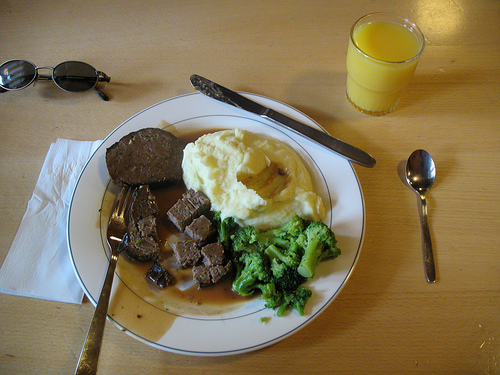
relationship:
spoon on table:
[394, 143, 471, 309] [10, 5, 498, 365]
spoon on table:
[405, 148, 437, 283] [10, 5, 498, 365]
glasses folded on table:
[0, 59, 111, 102] [10, 5, 498, 365]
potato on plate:
[180, 128, 327, 228] [330, 148, 374, 225]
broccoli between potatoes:
[212, 212, 342, 318] [175, 123, 325, 220]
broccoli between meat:
[212, 212, 342, 318] [104, 129, 217, 290]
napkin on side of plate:
[0, 138, 103, 305] [64, 88, 372, 359]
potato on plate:
[180, 128, 327, 228] [64, 88, 372, 359]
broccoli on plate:
[212, 212, 342, 318] [64, 88, 372, 359]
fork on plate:
[73, 182, 166, 373] [64, 88, 372, 359]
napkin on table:
[0, 138, 103, 305] [10, 5, 498, 365]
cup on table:
[343, 9, 428, 117] [0, 0, 472, 330]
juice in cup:
[344, 21, 420, 110] [328, 9, 435, 126]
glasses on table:
[0, 59, 111, 102] [10, 5, 498, 365]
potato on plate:
[192, 130, 313, 227] [337, 197, 384, 262]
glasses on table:
[0, 42, 101, 96] [2, 11, 150, 131]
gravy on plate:
[95, 120, 248, 344] [64, 88, 372, 359]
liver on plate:
[157, 180, 227, 265] [64, 88, 372, 359]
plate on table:
[80, 90, 384, 370] [10, 5, 498, 365]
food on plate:
[207, 210, 342, 324] [64, 88, 372, 359]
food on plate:
[101, 126, 346, 318] [64, 88, 372, 359]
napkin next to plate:
[5, 131, 103, 316] [64, 88, 372, 359]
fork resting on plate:
[73, 182, 140, 375] [64, 88, 372, 359]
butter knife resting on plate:
[188, 72, 378, 168] [52, 72, 375, 357]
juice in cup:
[344, 21, 420, 110] [343, 9, 428, 117]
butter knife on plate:
[188, 72, 376, 169] [64, 88, 372, 359]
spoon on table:
[405, 148, 437, 283] [347, 106, 487, 328]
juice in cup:
[360, 24, 414, 52] [344, 12, 425, 116]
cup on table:
[344, 12, 425, 116] [10, 5, 498, 365]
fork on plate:
[73, 182, 140, 375] [64, 88, 372, 359]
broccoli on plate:
[217, 217, 339, 314] [64, 88, 372, 359]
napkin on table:
[0, 138, 103, 305] [3, 8, 493, 108]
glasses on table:
[0, 59, 111, 102] [149, 0, 304, 58]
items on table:
[20, 29, 483, 372] [10, 5, 498, 365]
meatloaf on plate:
[98, 133, 230, 205] [46, 78, 360, 369]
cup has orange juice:
[344, 12, 425, 116] [348, 24, 418, 116]